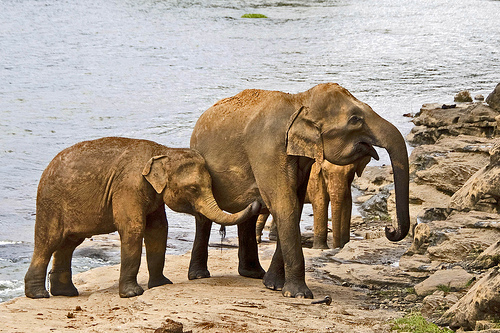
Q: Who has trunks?
A: Elephants.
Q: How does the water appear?
A: Calm.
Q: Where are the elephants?
A: Near the water.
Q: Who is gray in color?
A: The elephants.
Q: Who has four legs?
A: One elephant.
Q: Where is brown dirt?
A: On the ground.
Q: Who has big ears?
A: The elephants.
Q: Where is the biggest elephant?
A: In the middle.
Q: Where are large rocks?
A: On the shore.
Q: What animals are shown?
A: Elephants.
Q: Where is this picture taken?
A: An embankment.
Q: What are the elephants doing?
A: Walking as a family.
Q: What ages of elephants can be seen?
A: Baby and adult.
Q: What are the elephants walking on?
A: Stones.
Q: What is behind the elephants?
A: Water.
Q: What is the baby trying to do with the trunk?
A: Get mom's attention.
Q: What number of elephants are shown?
A: Three.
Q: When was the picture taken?
A: Morning.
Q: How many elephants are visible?
A: Three.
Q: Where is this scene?
A: A beach.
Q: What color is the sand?
A: Tan.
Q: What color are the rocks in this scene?
A: Brown and tan.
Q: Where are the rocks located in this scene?
A: In front of the elephants.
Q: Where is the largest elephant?
A: In the middle of the two smaller ones.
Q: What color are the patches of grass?
A: Green.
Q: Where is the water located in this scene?
A: In the rear of the elephants.